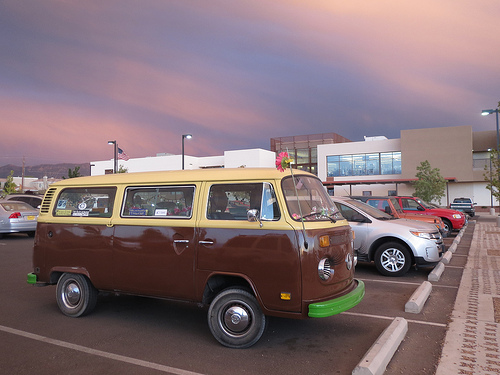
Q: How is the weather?
A: It is overcast.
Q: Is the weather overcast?
A: Yes, it is overcast.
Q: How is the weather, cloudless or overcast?
A: It is overcast.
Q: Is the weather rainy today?
A: No, it is overcast.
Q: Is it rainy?
A: No, it is overcast.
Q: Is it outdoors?
A: Yes, it is outdoors.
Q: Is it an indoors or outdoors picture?
A: It is outdoors.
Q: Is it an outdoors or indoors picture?
A: It is outdoors.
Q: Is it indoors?
A: No, it is outdoors.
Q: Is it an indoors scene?
A: No, it is outdoors.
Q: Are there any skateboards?
A: No, there are no skateboards.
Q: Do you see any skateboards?
A: No, there are no skateboards.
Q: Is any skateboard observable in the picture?
A: No, there are no skateboards.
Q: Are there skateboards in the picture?
A: No, there are no skateboards.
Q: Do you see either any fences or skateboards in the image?
A: No, there are no skateboards or fences.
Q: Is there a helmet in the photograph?
A: No, there are no helmets.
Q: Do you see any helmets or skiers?
A: No, there are no helmets or skiers.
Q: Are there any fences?
A: No, there are no fences.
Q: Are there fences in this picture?
A: No, there are no fences.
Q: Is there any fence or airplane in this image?
A: No, there are no fences or airplanes.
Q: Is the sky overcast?
A: Yes, the sky is overcast.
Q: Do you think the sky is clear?
A: No, the sky is overcast.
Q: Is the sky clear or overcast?
A: The sky is overcast.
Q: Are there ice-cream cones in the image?
A: No, there are no ice-cream cones.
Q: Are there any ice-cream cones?
A: No, there are no ice-cream cones.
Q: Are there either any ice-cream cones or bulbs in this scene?
A: No, there are no ice-cream cones or bulbs.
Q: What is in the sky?
A: The clouds are in the sky.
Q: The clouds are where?
A: The clouds are in the sky.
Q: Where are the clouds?
A: The clouds are in the sky.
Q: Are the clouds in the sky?
A: Yes, the clouds are in the sky.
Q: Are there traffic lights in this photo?
A: No, there are no traffic lights.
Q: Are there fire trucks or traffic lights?
A: No, there are no traffic lights or fire trucks.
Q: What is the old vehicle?
A: The vehicle is a van.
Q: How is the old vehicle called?
A: The vehicle is a van.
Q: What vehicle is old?
A: The vehicle is a van.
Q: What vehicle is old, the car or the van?
A: The van is old.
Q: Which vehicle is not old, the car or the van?
A: The car is not old.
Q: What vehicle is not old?
A: The vehicle is a car.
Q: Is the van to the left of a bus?
A: No, the van is to the left of the car.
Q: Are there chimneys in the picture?
A: No, there are no chimneys.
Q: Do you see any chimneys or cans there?
A: No, there are no chimneys or cans.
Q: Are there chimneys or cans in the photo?
A: No, there are no chimneys or cans.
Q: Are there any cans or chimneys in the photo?
A: No, there are no chimneys or cans.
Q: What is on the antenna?
A: The flower is on the antenna.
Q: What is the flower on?
A: The flower is on the antenna.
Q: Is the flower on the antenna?
A: Yes, the flower is on the antenna.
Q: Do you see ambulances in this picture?
A: No, there are no ambulances.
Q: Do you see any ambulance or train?
A: No, there are no ambulances or trains.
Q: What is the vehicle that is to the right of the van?
A: The vehicle is a car.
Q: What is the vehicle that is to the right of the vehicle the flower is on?
A: The vehicle is a car.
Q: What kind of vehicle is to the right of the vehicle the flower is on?
A: The vehicle is a car.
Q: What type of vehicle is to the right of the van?
A: The vehicle is a car.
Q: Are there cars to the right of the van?
A: Yes, there is a car to the right of the van.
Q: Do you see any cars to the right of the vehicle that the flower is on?
A: Yes, there is a car to the right of the van.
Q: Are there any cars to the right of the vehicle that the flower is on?
A: Yes, there is a car to the right of the van.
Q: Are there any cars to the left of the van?
A: No, the car is to the right of the van.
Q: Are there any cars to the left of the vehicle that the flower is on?
A: No, the car is to the right of the van.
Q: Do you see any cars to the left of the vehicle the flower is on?
A: No, the car is to the right of the van.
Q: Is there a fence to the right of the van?
A: No, there is a car to the right of the van.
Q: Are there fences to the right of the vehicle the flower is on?
A: No, there is a car to the right of the van.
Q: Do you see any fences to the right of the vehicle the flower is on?
A: No, there is a car to the right of the van.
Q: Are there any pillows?
A: No, there are no pillows.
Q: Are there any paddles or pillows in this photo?
A: No, there are no pillows or paddles.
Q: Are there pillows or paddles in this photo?
A: No, there are no pillows or paddles.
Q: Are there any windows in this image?
A: Yes, there is a window.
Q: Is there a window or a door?
A: Yes, there is a window.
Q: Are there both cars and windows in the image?
A: Yes, there are both a window and a car.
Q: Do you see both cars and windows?
A: Yes, there are both a window and a car.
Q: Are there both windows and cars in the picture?
A: Yes, there are both a window and a car.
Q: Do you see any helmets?
A: No, there are no helmets.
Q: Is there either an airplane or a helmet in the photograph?
A: No, there are no helmets or airplanes.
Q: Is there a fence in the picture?
A: No, there are no fences.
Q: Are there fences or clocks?
A: No, there are no fences or clocks.